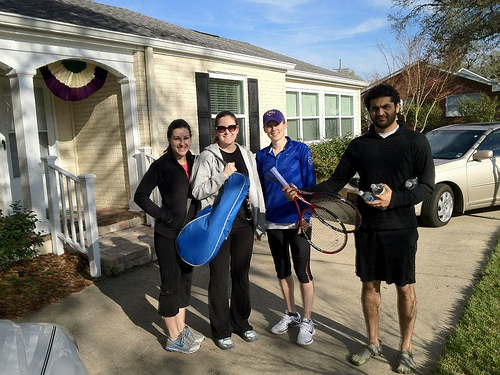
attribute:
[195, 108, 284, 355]
woman — standing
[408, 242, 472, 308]
driveway — paved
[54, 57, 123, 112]
bunting — red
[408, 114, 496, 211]
car — gold, silver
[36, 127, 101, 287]
rail — white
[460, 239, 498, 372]
grass — green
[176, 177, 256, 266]
bag — blue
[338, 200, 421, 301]
shorts — black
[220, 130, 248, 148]
sunglasses — black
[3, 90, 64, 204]
door — white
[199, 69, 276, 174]
shutters — black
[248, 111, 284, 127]
cap — purple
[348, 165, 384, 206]
water — in bottles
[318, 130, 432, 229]
shirt — black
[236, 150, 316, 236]
shirt — blue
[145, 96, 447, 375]
people — grouped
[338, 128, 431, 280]
outfit — black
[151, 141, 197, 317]
outfit — black